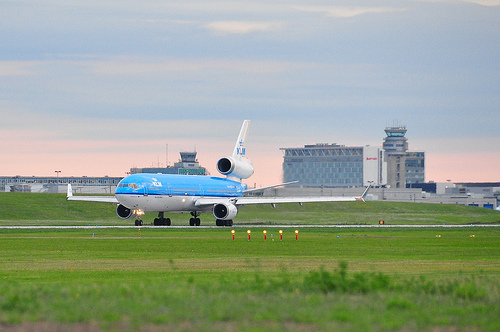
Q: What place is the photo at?
A: It is at the airport.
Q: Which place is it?
A: It is an airport.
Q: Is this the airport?
A: Yes, it is the airport.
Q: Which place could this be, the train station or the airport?
A: It is the airport.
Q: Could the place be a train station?
A: No, it is an airport.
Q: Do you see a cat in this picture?
A: No, there are no cats.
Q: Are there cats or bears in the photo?
A: No, there are no cats or bears.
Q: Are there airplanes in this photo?
A: Yes, there is an airplane.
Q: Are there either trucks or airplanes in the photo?
A: Yes, there is an airplane.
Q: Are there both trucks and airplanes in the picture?
A: No, there is an airplane but no trucks.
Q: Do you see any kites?
A: No, there are no kites.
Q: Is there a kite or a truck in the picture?
A: No, there are no kites or trucks.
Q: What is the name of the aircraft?
A: The aircraft is an airplane.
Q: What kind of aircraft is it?
A: The aircraft is an airplane.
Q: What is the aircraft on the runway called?
A: The aircraft is an airplane.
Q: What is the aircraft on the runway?
A: The aircraft is an airplane.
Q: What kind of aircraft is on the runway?
A: The aircraft is an airplane.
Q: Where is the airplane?
A: The airplane is on the runway.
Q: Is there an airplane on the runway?
A: Yes, there is an airplane on the runway.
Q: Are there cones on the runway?
A: No, there is an airplane on the runway.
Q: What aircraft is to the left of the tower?
A: The aircraft is an airplane.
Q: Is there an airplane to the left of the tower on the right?
A: Yes, there is an airplane to the left of the tower.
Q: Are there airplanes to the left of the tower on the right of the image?
A: Yes, there is an airplane to the left of the tower.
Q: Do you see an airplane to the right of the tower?
A: No, the airplane is to the left of the tower.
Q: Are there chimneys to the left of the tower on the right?
A: No, there is an airplane to the left of the tower.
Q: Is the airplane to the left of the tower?
A: Yes, the airplane is to the left of the tower.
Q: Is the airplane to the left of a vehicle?
A: No, the airplane is to the left of the tower.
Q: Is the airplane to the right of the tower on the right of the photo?
A: No, the airplane is to the left of the tower.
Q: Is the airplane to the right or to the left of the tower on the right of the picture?
A: The airplane is to the left of the tower.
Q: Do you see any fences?
A: No, there are no fences.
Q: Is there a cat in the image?
A: No, there are no cats.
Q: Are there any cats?
A: No, there are no cats.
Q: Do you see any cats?
A: No, there are no cats.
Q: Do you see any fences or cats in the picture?
A: No, there are no cats or fences.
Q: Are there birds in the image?
A: No, there are no birds.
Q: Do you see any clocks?
A: No, there are no clocks.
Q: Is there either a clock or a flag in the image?
A: No, there are no clocks or flags.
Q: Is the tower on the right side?
A: Yes, the tower is on the right of the image.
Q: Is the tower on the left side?
A: No, the tower is on the right of the image.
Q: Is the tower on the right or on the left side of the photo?
A: The tower is on the right of the image.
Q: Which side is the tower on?
A: The tower is on the right of the image.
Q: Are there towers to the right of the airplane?
A: Yes, there is a tower to the right of the airplane.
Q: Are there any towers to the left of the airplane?
A: No, the tower is to the right of the airplane.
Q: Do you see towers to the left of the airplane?
A: No, the tower is to the right of the airplane.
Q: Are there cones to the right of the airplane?
A: No, there is a tower to the right of the airplane.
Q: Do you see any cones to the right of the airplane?
A: No, there is a tower to the right of the airplane.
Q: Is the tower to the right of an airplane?
A: Yes, the tower is to the right of an airplane.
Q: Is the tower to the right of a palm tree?
A: No, the tower is to the right of an airplane.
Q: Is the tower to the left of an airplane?
A: No, the tower is to the right of an airplane.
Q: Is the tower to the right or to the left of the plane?
A: The tower is to the right of the plane.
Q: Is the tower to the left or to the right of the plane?
A: The tower is to the right of the plane.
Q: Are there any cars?
A: No, there are no cars.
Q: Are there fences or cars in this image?
A: No, there are no cars or fences.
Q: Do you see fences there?
A: No, there are no fences.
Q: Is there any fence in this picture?
A: No, there are no fences.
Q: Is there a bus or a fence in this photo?
A: No, there are no fences or buses.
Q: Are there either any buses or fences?
A: No, there are no fences or buses.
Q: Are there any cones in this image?
A: No, there are no cones.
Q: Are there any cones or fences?
A: No, there are no cones or fences.